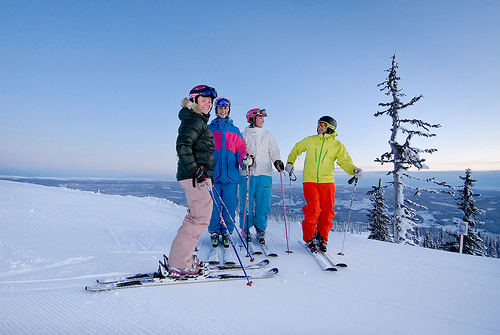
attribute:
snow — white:
[2, 178, 499, 331]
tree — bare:
[375, 54, 435, 245]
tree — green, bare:
[447, 168, 487, 252]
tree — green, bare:
[366, 177, 391, 244]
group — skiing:
[169, 84, 354, 271]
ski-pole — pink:
[280, 170, 291, 252]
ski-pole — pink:
[241, 168, 252, 245]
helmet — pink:
[247, 108, 267, 119]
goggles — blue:
[260, 108, 267, 117]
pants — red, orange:
[301, 182, 334, 241]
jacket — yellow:
[288, 133, 357, 183]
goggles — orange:
[318, 120, 328, 128]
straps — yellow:
[329, 124, 337, 132]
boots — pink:
[169, 257, 198, 276]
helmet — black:
[319, 115, 337, 132]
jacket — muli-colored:
[212, 117, 245, 181]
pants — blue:
[212, 181, 237, 233]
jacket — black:
[177, 101, 214, 179]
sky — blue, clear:
[2, 1, 493, 176]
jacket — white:
[244, 125, 277, 175]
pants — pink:
[172, 178, 214, 274]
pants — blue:
[241, 175, 273, 236]